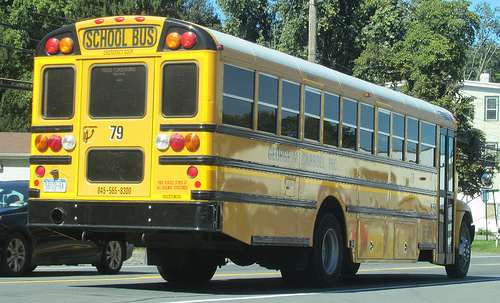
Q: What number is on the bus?
A: 79.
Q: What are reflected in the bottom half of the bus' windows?
A: Trees.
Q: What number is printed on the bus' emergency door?
A: 79.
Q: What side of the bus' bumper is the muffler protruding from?
A: Left.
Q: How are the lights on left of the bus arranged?
A: Orange, red, white, side-by-side.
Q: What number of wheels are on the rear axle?
A: 4.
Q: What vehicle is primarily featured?
A: School Bus.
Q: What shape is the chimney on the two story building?
A: Square.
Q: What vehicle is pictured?
A: School bus.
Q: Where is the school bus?
A: On the road.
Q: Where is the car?
A: Behind the school bus.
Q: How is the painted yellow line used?
A: To designate traffic lanes.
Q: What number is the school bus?
A: 79.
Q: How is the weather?
A: Sunny.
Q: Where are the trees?
A: On the other side of the road.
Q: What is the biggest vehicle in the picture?
A: School bus.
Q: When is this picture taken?
A: Daytime.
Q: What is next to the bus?
A: Car.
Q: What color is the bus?
A: Yellow.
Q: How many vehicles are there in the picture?
A: Two.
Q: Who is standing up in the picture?
A: No one.